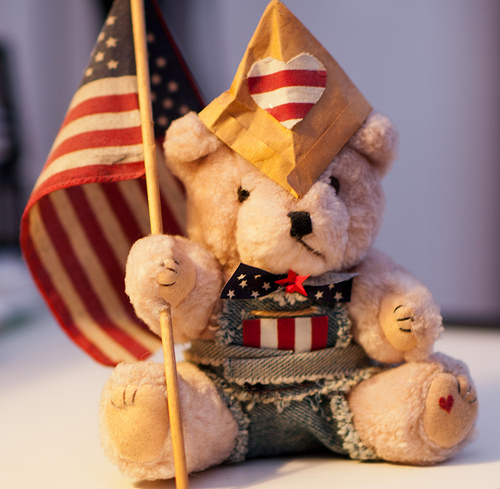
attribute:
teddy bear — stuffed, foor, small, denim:
[98, 3, 476, 487]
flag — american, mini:
[18, 7, 216, 487]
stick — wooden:
[129, 0, 191, 489]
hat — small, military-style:
[197, 5, 375, 200]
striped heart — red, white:
[249, 52, 326, 133]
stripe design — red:
[242, 311, 332, 349]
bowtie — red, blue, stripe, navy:
[224, 267, 352, 311]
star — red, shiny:
[275, 269, 309, 299]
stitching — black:
[114, 390, 140, 416]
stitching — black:
[255, 214, 329, 262]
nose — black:
[289, 210, 317, 240]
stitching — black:
[231, 172, 344, 208]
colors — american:
[239, 3, 336, 355]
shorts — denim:
[177, 360, 376, 465]